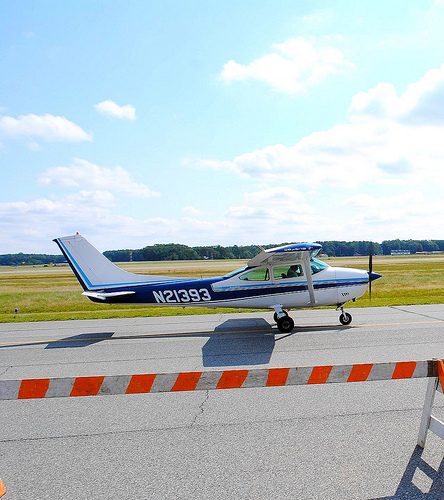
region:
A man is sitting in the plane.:
[44, 220, 380, 344]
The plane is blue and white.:
[52, 226, 388, 337]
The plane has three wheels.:
[45, 220, 395, 346]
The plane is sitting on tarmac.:
[5, 218, 442, 497]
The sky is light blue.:
[0, 3, 442, 246]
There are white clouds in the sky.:
[2, 3, 442, 246]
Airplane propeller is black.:
[48, 211, 398, 341]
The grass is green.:
[0, 248, 442, 323]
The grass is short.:
[0, 245, 441, 324]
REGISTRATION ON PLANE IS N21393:
[149, 286, 231, 305]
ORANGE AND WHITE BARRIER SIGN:
[0, 349, 442, 441]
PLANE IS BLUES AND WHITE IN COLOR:
[48, 215, 384, 318]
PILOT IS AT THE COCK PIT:
[254, 254, 337, 278]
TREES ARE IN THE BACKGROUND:
[2, 239, 442, 266]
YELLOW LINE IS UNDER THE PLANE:
[6, 308, 436, 347]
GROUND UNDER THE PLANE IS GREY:
[15, 331, 420, 495]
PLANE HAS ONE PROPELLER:
[357, 246, 404, 306]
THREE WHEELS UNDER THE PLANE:
[261, 301, 373, 335]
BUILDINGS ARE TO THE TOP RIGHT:
[388, 237, 439, 263]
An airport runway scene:
[8, 81, 441, 455]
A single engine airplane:
[48, 223, 389, 340]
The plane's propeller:
[362, 236, 385, 314]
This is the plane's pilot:
[282, 259, 304, 282]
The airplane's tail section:
[51, 230, 146, 320]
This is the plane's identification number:
[147, 284, 213, 309]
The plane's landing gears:
[266, 301, 359, 334]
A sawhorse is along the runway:
[13, 353, 443, 453]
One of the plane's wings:
[246, 236, 327, 272]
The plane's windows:
[238, 256, 331, 283]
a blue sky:
[70, 18, 191, 68]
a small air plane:
[52, 228, 382, 325]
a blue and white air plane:
[49, 234, 391, 338]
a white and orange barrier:
[0, 354, 441, 460]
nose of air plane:
[372, 239, 381, 300]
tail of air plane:
[50, 232, 127, 286]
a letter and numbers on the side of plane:
[142, 286, 214, 301]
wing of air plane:
[244, 239, 326, 264]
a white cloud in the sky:
[206, 20, 359, 97]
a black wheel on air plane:
[278, 314, 293, 331]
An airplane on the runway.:
[52, 233, 384, 333]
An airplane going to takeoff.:
[51, 232, 383, 334]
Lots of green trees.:
[2, 237, 443, 267]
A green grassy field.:
[0, 253, 442, 323]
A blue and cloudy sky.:
[2, 1, 443, 253]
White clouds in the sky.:
[1, 3, 441, 253]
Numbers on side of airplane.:
[151, 286, 213, 303]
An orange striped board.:
[2, 355, 443, 399]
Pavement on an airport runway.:
[2, 301, 443, 498]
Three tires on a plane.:
[273, 308, 352, 334]